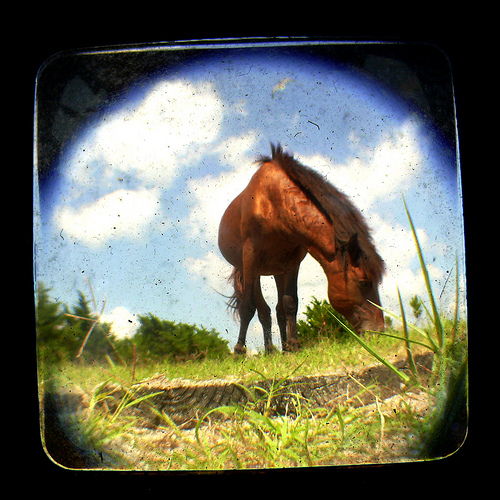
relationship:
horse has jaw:
[207, 141, 385, 353] [309, 288, 382, 350]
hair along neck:
[273, 147, 348, 203] [261, 159, 364, 264]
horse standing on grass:
[207, 141, 385, 353] [42, 302, 461, 459]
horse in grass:
[207, 141, 385, 353] [324, 191, 459, 395]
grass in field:
[324, 191, 459, 395] [48, 332, 438, 466]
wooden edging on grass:
[150, 364, 363, 428] [38, 322, 470, 472]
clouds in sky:
[98, 80, 224, 180] [36, 51, 468, 338]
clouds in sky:
[217, 132, 247, 163] [36, 51, 468, 338]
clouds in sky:
[53, 185, 166, 250] [36, 51, 468, 338]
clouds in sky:
[321, 125, 436, 201] [36, 51, 468, 338]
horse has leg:
[208, 126, 379, 339] [232, 254, 258, 360]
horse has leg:
[208, 126, 379, 339] [235, 274, 276, 357]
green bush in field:
[143, 315, 220, 362] [40, 319, 472, 467]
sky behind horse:
[157, 68, 377, 143] [207, 141, 385, 353]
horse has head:
[207, 141, 385, 353] [305, 254, 420, 366]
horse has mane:
[207, 141, 385, 353] [265, 144, 379, 276]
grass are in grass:
[324, 191, 459, 395] [324, 191, 459, 395]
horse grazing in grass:
[207, 141, 385, 353] [98, 328, 420, 463]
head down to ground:
[326, 254, 386, 338] [33, 328, 468, 471]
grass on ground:
[42, 340, 458, 460] [51, 336, 467, 475]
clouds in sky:
[94, 80, 224, 180] [63, 77, 462, 202]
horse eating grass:
[207, 141, 385, 353] [38, 322, 470, 472]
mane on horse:
[250, 140, 388, 285] [211, 138, 393, 350]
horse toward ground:
[207, 141, 385, 353] [37, 320, 487, 470]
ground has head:
[37, 320, 487, 470] [325, 247, 382, 336]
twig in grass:
[57, 243, 147, 354] [82, 321, 322, 407]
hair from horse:
[224, 282, 244, 315] [207, 141, 385, 353]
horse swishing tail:
[207, 141, 385, 353] [224, 263, 245, 320]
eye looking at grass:
[356, 277, 373, 294] [152, 395, 348, 459]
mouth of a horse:
[345, 307, 398, 347] [181, 109, 432, 394]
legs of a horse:
[220, 240, 308, 355] [207, 141, 385, 353]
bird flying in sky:
[265, 71, 295, 96] [36, 51, 468, 338]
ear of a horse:
[333, 207, 368, 272] [207, 141, 385, 353]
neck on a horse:
[268, 159, 373, 273] [207, 141, 385, 353]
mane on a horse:
[269, 148, 386, 281] [207, 141, 385, 353]